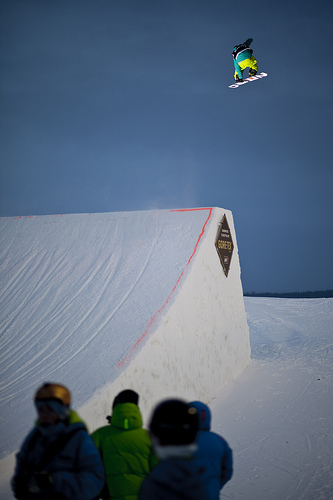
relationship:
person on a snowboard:
[215, 33, 271, 95] [221, 72, 270, 90]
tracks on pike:
[26, 234, 127, 347] [4, 204, 247, 380]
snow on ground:
[247, 297, 331, 497] [239, 411, 324, 457]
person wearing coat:
[94, 385, 155, 498] [88, 401, 162, 499]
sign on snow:
[212, 208, 237, 280] [175, 294, 230, 347]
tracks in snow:
[0, 220, 170, 411] [256, 319, 319, 426]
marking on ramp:
[164, 201, 213, 294] [4, 205, 253, 375]